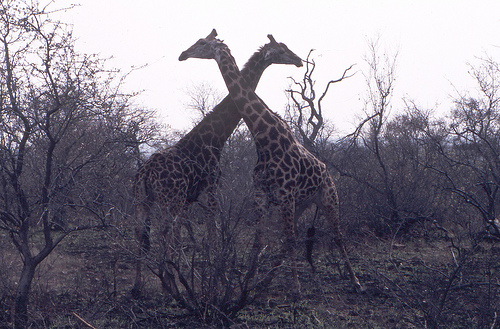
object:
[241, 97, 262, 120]
spots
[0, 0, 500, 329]
forest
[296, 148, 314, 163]
spots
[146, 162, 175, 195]
spots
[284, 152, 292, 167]
spot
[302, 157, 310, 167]
spot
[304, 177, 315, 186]
spot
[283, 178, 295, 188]
spot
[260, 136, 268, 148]
spot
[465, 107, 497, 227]
tree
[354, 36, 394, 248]
tree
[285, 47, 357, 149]
tree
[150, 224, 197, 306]
tree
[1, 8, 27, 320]
tree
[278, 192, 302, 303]
4 legs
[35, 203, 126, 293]
branch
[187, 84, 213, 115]
tree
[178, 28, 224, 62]
giraffe head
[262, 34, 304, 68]
giraffe head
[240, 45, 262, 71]
mane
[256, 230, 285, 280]
trees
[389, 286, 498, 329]
twigs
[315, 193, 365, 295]
leg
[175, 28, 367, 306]
animal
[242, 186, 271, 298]
leg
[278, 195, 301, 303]
leg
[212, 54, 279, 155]
neck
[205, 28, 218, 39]
ear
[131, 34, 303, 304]
animal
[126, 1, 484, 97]
sky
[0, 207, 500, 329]
land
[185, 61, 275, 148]
neck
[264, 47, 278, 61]
ear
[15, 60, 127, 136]
branches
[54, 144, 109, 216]
tree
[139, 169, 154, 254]
tail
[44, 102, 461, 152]
leaves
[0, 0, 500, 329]
savannah